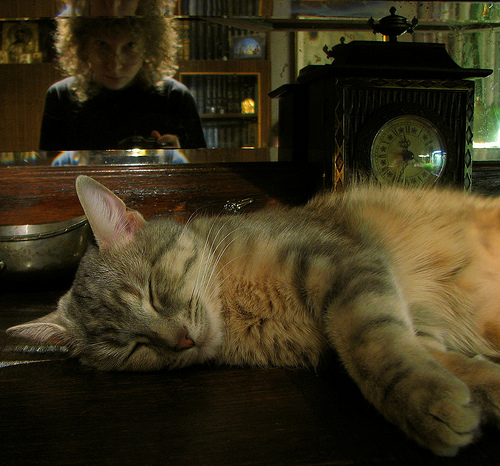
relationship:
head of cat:
[0, 149, 230, 379] [10, 148, 496, 454]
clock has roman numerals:
[351, 96, 457, 202] [377, 111, 434, 151]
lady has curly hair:
[20, 0, 218, 155] [58, 9, 89, 97]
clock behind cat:
[351, 96, 457, 202] [10, 148, 496, 454]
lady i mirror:
[20, 0, 218, 155] [6, 6, 286, 169]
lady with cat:
[20, 0, 218, 155] [10, 148, 496, 454]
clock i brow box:
[351, 96, 457, 202] [254, 9, 491, 207]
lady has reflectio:
[20, 0, 218, 155] [7, 1, 297, 31]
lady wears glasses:
[20, 0, 218, 155] [70, 32, 157, 65]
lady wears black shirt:
[20, 0, 218, 155] [32, 71, 219, 161]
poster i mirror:
[6, 20, 76, 82] [6, 6, 286, 169]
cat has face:
[10, 148, 496, 454] [93, 253, 232, 366]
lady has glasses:
[20, 0, 218, 155] [70, 32, 157, 65]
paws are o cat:
[411, 352, 496, 456] [10, 148, 496, 454]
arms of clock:
[387, 155, 421, 188] [351, 96, 457, 202]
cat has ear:
[10, 148, 496, 454] [64, 163, 152, 260]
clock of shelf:
[351, 96, 457, 202] [5, 299, 496, 411]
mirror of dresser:
[6, 6, 286, 169] [0, 155, 316, 302]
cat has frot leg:
[10, 148, 496, 454] [286, 222, 487, 463]